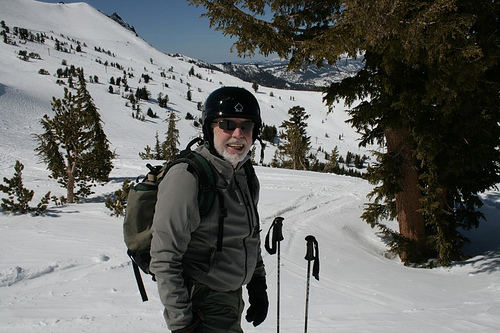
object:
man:
[148, 86, 269, 333]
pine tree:
[183, 0, 499, 269]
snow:
[292, 174, 355, 220]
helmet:
[201, 86, 263, 144]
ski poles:
[262, 216, 321, 333]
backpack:
[121, 137, 261, 303]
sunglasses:
[212, 119, 255, 131]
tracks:
[260, 180, 486, 333]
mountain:
[0, 0, 378, 165]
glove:
[243, 297, 269, 326]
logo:
[234, 103, 244, 113]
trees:
[28, 71, 116, 205]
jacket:
[149, 141, 269, 333]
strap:
[131, 263, 150, 303]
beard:
[213, 137, 253, 164]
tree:
[278, 105, 313, 170]